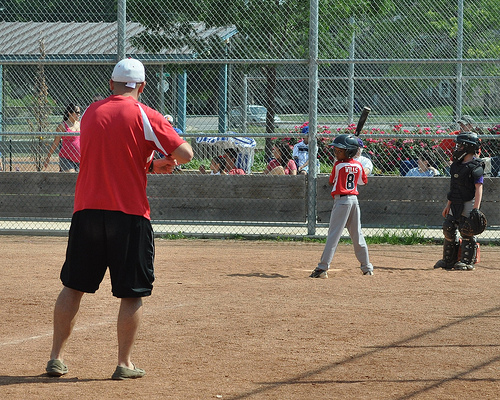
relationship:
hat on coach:
[107, 55, 148, 85] [37, 51, 199, 382]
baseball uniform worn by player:
[58, 93, 188, 298] [309, 132, 375, 276]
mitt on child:
[461, 208, 487, 238] [307, 132, 375, 279]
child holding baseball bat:
[307, 132, 375, 279] [307, 102, 386, 279]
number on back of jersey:
[339, 172, 363, 199] [317, 164, 374, 198]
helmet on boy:
[332, 135, 359, 156] [431, 131, 484, 270]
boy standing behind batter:
[431, 131, 484, 270] [310, 101, 374, 276]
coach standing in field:
[37, 51, 199, 382] [1, 232, 498, 398]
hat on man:
[111, 58, 146, 89] [39, 57, 196, 384]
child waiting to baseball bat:
[307, 132, 376, 279] [353, 105, 372, 136]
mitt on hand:
[468, 208, 487, 236] [474, 178, 481, 210]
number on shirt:
[346, 174, 354, 190] [328, 161, 368, 196]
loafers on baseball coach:
[32, 346, 192, 394] [65, 59, 223, 283]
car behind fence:
[221, 90, 290, 139] [200, 109, 260, 265]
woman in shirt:
[260, 135, 300, 175] [63, 100, 73, 158]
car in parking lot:
[229, 103, 282, 130] [232, 150, 248, 172]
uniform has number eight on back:
[315, 160, 374, 272] [338, 164, 356, 192]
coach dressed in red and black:
[46, 57, 193, 382] [112, 218, 143, 270]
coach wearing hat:
[46, 57, 193, 382] [108, 58, 143, 98]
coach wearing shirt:
[46, 57, 193, 382] [77, 89, 178, 222]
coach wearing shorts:
[46, 57, 193, 382] [58, 210, 154, 297]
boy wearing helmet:
[431, 131, 484, 270] [324, 125, 364, 241]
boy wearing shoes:
[431, 131, 484, 270] [29, 343, 161, 385]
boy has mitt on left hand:
[431, 131, 484, 270] [434, 193, 484, 257]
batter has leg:
[311, 136, 374, 276] [308, 200, 349, 285]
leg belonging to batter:
[317, 202, 347, 273] [283, 87, 391, 273]